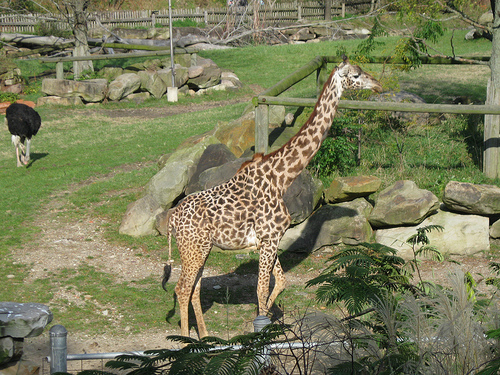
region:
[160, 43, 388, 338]
giraffe walking in enclosure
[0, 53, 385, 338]
giraffe and ostrich in enclosure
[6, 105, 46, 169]
ostrich with head near ground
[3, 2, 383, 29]
wooden slat fence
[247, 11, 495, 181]
protective fence around tree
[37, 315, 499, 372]
metal and wire fence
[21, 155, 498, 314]
dirt path in grass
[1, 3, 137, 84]
tree without leaves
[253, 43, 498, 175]
fence made with untreated wood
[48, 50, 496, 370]
giraffe walking along fence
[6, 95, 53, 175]
the ostrich has black feathers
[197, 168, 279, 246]
the spots are white and brown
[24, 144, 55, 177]
shadow is on the ground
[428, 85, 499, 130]
the fence is wooden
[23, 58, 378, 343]
the animas are in a zoo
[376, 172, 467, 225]
the rocks are huge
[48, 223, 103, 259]
the patch has no grass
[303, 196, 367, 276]
shadow is on the rock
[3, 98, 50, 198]
the ostrich is grazing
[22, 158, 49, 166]
the beak is orange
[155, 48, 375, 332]
giraffe with long neck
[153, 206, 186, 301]
tail of a giraffe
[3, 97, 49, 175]
ostrich with head down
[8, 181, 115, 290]
bare spot in grass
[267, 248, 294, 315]
bent knee on giraffe leg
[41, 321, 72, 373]
post of metal fence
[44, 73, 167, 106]
pile of large rocks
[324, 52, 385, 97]
profile of a giraffe's head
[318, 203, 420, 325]
green foliage in front of rocks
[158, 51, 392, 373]
giraffe behind a metal fence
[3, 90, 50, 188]
this is an ostrich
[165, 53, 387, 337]
this is a giraffe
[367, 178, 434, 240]
this is a rock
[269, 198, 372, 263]
this is a rock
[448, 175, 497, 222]
this is a rock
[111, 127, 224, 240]
this is a rock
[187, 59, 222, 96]
this is a rock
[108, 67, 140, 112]
this is a rock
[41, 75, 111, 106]
this is a rock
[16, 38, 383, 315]
giraffe and an ostrich in a zoo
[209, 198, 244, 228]
brown spots on giraffe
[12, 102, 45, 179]
ostrich grazing on the grass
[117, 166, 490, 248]
large grey rocks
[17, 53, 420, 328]
picture of animals in a zoo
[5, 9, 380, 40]
long brown wooden fence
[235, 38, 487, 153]
wooden barrier built around tree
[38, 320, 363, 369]
silver chain link fence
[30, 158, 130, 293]
small path in a grassy area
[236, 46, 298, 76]
green grassy field